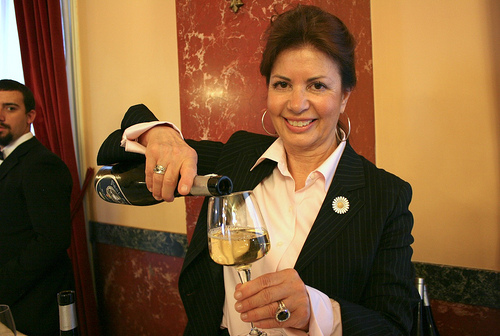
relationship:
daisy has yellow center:
[332, 195, 351, 216] [338, 201, 344, 209]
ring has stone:
[274, 301, 291, 322] [281, 312, 288, 318]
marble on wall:
[174, 1, 361, 305] [73, 0, 496, 273]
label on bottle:
[94, 175, 130, 209] [96, 163, 232, 209]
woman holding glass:
[102, 2, 427, 335] [205, 191, 271, 335]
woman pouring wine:
[102, 2, 427, 335] [210, 234, 269, 268]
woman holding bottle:
[102, 2, 427, 335] [96, 163, 232, 209]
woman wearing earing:
[102, 2, 427, 335] [262, 108, 277, 143]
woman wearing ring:
[102, 2, 427, 335] [274, 301, 291, 322]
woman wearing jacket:
[102, 2, 427, 335] [100, 102, 424, 331]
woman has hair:
[102, 2, 427, 335] [259, 5, 358, 88]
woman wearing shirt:
[102, 2, 427, 335] [119, 118, 348, 326]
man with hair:
[3, 79, 74, 333] [1, 80, 37, 114]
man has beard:
[3, 79, 74, 333] [1, 132, 14, 144]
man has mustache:
[3, 79, 74, 333] [3, 121, 10, 129]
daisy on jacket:
[332, 195, 351, 216] [100, 102, 424, 331]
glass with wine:
[205, 191, 271, 335] [210, 234, 269, 268]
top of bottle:
[217, 175, 237, 197] [96, 163, 232, 209]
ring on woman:
[274, 301, 291, 322] [102, 2, 427, 335]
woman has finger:
[102, 2, 427, 335] [239, 301, 303, 323]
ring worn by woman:
[274, 301, 291, 322] [102, 2, 427, 335]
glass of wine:
[205, 191, 271, 335] [210, 234, 269, 268]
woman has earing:
[102, 2, 427, 335] [262, 108, 277, 143]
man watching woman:
[3, 79, 74, 333] [102, 2, 427, 335]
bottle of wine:
[96, 163, 232, 209] [210, 234, 269, 268]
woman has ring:
[102, 2, 427, 335] [274, 301, 291, 322]